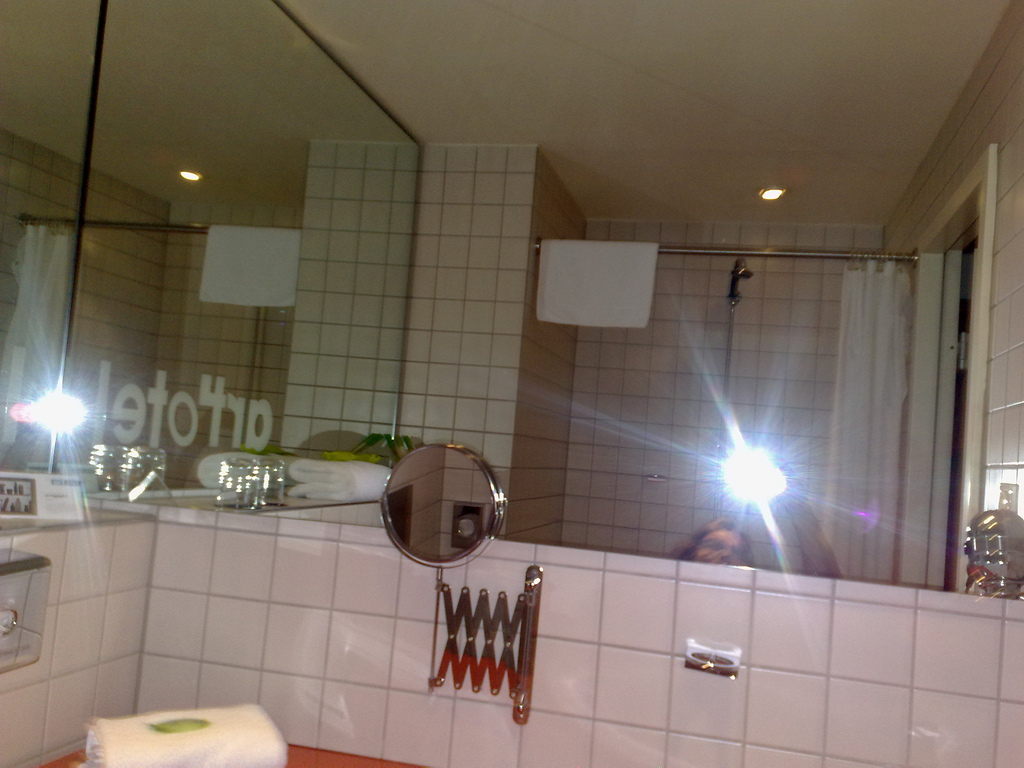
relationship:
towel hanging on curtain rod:
[534, 234, 655, 329] [531, 237, 921, 267]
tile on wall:
[200, 564, 343, 677] [172, 519, 393, 738]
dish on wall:
[673, 627, 749, 680] [573, 553, 861, 765]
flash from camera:
[718, 435, 794, 513] [723, 471, 790, 510]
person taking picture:
[682, 515, 771, 559] [10, 7, 1019, 761]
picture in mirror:
[10, 7, 1019, 761] [122, 22, 1019, 548]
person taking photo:
[677, 515, 794, 580] [10, 11, 1017, 759]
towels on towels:
[78, 694, 282, 764] [79, 694, 282, 764]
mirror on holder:
[371, 443, 508, 571] [410, 565, 542, 734]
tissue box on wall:
[0, 547, 50, 681] [2, 513, 156, 764]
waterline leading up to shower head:
[707, 310, 742, 471] [721, 262, 761, 319]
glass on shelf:
[205, 448, 253, 515] [86, 484, 367, 532]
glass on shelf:
[253, 452, 290, 507] [86, 484, 367, 532]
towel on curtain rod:
[534, 234, 655, 329] [531, 238, 931, 267]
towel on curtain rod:
[188, 217, 305, 308] [11, 199, 212, 236]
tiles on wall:
[194, 586, 396, 693] [0, 523, 992, 765]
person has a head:
[675, 492, 844, 583] [678, 519, 758, 567]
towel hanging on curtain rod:
[534, 234, 655, 329] [652, 240, 728, 260]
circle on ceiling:
[751, 182, 795, 204] [765, 53, 887, 168]